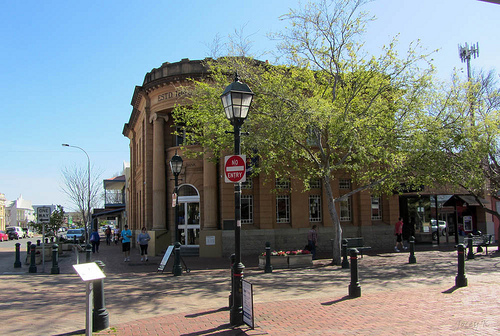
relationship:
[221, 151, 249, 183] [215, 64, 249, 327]
sign on street lamp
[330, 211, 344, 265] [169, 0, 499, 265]
trunk of tree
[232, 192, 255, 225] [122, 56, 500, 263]
window in building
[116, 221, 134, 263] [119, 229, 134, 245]
man wearing shirt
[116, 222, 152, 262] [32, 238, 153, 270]
people on sidewalk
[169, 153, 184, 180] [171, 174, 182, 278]
light on pole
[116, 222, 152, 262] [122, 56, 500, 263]
people next to building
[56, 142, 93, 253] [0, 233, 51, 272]
lightpost over street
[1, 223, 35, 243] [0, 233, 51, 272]
cars parked on street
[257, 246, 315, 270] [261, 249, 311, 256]
planter with flowers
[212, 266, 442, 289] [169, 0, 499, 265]
shadow of tree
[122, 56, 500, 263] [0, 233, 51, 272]
building on street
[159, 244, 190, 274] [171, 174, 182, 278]
street sign by pole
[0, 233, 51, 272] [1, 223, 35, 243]
street with cars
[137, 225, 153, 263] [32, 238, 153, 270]
people on sidewalk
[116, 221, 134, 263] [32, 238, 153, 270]
man on sidewalk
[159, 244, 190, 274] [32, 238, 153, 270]
street sign on sidewalk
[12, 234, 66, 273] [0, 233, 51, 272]
posts by street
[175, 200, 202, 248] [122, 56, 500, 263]
door on building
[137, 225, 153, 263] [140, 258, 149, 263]
people wearing sneakers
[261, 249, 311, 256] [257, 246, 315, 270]
flowers in planter